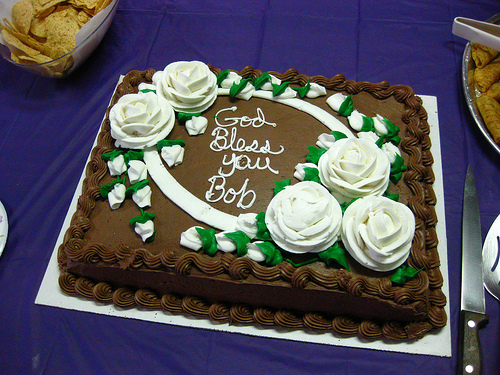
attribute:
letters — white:
[203, 104, 275, 211]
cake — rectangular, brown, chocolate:
[63, 64, 451, 345]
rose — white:
[260, 177, 341, 256]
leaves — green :
[227, 229, 274, 263]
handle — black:
[457, 309, 493, 369]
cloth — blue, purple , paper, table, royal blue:
[3, 2, 495, 372]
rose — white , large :
[269, 179, 342, 256]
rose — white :
[269, 175, 336, 245]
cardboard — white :
[36, 68, 450, 358]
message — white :
[201, 108, 278, 217]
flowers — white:
[260, 125, 418, 277]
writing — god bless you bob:
[186, 98, 297, 227]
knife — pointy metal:
[444, 156, 484, 373]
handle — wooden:
[454, 308, 495, 373]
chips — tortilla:
[6, 2, 76, 67]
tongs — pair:
[444, 5, 497, 43]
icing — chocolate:
[59, 235, 206, 316]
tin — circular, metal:
[448, 25, 498, 161]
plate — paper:
[0, 196, 12, 268]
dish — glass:
[4, 0, 117, 85]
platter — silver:
[455, 16, 498, 165]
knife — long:
[450, 155, 492, 373]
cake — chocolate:
[47, 51, 446, 360]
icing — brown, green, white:
[91, 60, 417, 295]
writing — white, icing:
[193, 94, 290, 213]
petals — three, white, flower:
[266, 125, 417, 292]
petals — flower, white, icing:
[107, 59, 217, 149]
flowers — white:
[261, 126, 427, 292]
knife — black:
[440, 147, 491, 371]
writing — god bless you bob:
[201, 101, 288, 222]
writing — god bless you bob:
[206, 96, 293, 225]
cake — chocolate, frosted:
[37, 60, 458, 372]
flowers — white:
[270, 130, 415, 271]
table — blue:
[1, 3, 489, 373]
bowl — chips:
[1, 3, 121, 83]